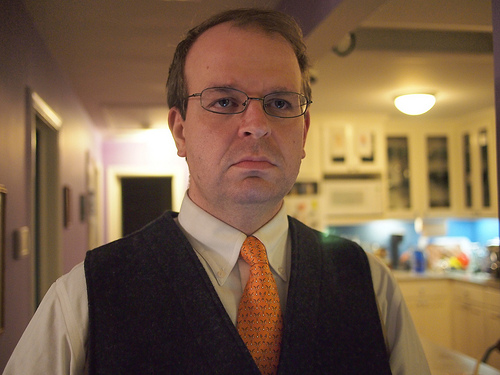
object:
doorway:
[117, 175, 176, 237]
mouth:
[227, 156, 278, 169]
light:
[391, 92, 437, 117]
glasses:
[176, 84, 313, 120]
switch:
[14, 225, 29, 259]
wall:
[0, 0, 107, 375]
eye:
[206, 95, 239, 108]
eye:
[265, 97, 291, 113]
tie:
[230, 235, 285, 375]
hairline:
[177, 16, 307, 119]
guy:
[0, 8, 435, 375]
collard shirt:
[0, 187, 434, 375]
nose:
[237, 94, 272, 138]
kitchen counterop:
[393, 270, 500, 375]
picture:
[327, 125, 345, 157]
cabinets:
[320, 114, 386, 179]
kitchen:
[0, 0, 500, 375]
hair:
[166, 7, 313, 121]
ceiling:
[24, 0, 498, 131]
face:
[180, 18, 308, 206]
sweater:
[80, 207, 391, 375]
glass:
[425, 134, 450, 207]